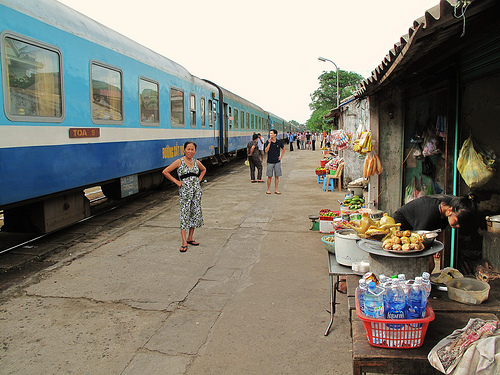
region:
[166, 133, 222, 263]
woman looking at camera posing in front of train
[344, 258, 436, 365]
red basket full of bottled water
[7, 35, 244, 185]
large blue and white train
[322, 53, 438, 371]
street vendors at train stop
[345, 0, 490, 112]
brown tin roof of building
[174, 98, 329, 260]
numerous people waiting on platform in front of train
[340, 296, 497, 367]
old wooden brown tables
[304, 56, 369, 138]
very large tree with green leaves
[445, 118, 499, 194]
yellow bag hanging inside building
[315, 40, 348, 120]
modern light to illuminate train platform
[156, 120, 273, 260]
Woman standing on road.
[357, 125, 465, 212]
Bananas on the wall.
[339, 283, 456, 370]
Water in a basket.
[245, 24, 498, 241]
Trees behind a building.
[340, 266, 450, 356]
Red basket with water.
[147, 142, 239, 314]
Woman wearing a dress.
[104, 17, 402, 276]
Train on the track.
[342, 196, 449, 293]
Yellow food on plates.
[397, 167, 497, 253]
Woman bending over a table.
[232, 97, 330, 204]
People in the distance.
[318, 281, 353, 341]
curved edge of silver table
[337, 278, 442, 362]
red plastic tub on brown table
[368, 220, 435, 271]
plate of delicious pastries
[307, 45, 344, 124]
long curved silver street light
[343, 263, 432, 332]
tall bottles of water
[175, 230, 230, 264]
black flip flops on woman's feet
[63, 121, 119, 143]
small brown sign on passenger train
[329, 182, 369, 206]
variety of fruits in front of stall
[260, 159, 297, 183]
man wearing gray shorts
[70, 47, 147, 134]
large clear window in two tone blue train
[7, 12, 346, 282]
Train on the tracks.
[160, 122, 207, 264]
Woman with flowered dress and flip flops.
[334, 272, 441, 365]
Red laundry basket with bottles of water.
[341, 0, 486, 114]
Roof made of clay tiles.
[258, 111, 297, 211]
Man with a black shirt and grey shorts.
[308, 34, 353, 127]
Light post at the end of the buildings.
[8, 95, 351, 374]
Sidewalk made of concrete.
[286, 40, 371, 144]
Tree in the background.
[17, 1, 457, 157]
The sky is grey.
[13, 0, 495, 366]
Photo taken during the day.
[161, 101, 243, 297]
lady standing with hands on hips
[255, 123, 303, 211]
man standing next to train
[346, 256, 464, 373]
red container with water bottles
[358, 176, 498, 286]
lady bending over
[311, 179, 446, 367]
food for sale on side of street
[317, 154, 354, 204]
chair on side of street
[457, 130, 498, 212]
yellow plastic bag hanging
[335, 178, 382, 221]
green bananas on side of street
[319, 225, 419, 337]
table with food on it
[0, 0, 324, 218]
blue and white train